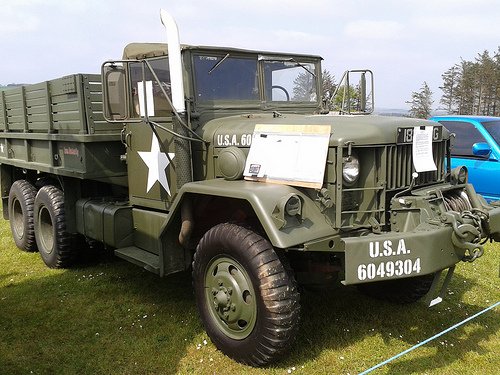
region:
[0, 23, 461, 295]
this is a lorry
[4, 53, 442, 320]
the lorry is parked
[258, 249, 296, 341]
this is the wheel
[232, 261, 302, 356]
the wheel is black in color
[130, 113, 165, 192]
this is the door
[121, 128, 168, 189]
the door is closed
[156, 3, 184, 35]
this is the chimney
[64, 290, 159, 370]
this is the grass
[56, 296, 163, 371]
the grass is short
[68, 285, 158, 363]
the grass is green in color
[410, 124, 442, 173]
flyer attached to front of vehicle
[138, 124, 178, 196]
star emblem on door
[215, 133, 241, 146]
u.s.a on side of hood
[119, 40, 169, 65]
tarp roof attached to truck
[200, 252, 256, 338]
military green hub caps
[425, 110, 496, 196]
blue truck beside military vehicle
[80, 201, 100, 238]
dent in gas tank of vehicle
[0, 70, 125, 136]
slats in sides of truck bed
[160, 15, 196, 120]
white exhaust pipe for truck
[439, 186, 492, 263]
tow chain attached to truck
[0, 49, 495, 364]
a parked army vehicle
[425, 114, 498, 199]
a blue truck with tinted windows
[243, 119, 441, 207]
signs on the army truck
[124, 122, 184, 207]
a white star on the door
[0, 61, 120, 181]
a framed bed on the truck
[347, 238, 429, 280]
the bumper has letters and numbers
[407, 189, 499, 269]
a wench on the front of the truck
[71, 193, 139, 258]
fuel tank on the side of the truck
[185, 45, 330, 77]
wipers at the top of the windshield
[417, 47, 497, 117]
pine trees in the distance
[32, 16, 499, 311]
an army truck for driving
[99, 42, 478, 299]
the army truck is green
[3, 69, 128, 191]
the cab on the truck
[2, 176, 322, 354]
tires on the truck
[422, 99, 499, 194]
a blue car next to the truck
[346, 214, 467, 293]
the truck's tag number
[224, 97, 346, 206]
a sign on the truck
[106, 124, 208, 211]
a star on the truck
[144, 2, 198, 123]
a white exhaust pipe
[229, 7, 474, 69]
overcast skies above the area